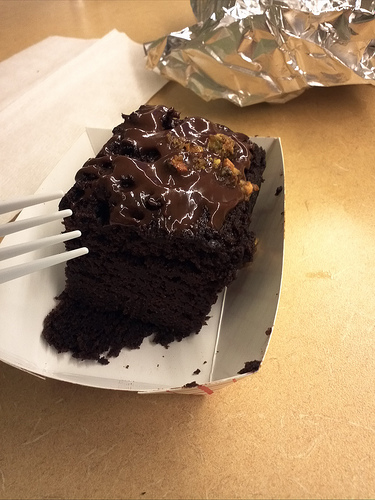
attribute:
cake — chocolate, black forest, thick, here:
[31, 99, 276, 367]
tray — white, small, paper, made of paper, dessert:
[0, 124, 288, 395]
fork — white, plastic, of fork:
[0, 197, 91, 290]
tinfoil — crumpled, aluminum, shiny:
[147, 0, 374, 110]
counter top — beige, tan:
[0, 1, 373, 498]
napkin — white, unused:
[0, 28, 168, 223]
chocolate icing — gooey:
[79, 102, 253, 227]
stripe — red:
[195, 384, 216, 395]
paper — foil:
[141, 2, 363, 111]